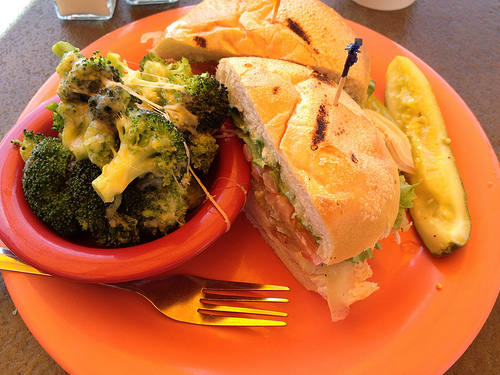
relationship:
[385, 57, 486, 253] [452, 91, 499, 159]
pickle on plate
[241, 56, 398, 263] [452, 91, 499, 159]
sandwhich on plate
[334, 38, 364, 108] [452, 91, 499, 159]
toothpick on plate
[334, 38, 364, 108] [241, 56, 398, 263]
toothpick on sandwhich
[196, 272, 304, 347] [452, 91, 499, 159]
fork on plate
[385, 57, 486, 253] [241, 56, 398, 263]
pickle near sandwhich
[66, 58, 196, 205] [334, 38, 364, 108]
brocolli near toothpick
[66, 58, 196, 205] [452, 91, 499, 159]
brocolli on plate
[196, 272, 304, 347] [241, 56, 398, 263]
fork near sandwhich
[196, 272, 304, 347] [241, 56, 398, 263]
fork next to sandwhich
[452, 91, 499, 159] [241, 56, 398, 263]
plate holding sandwhich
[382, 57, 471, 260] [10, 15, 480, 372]
pickle on plate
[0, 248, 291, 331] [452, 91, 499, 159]
fork on plate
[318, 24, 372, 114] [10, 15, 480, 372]
toothpick on plate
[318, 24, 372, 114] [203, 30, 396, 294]
toothpick in sandwich